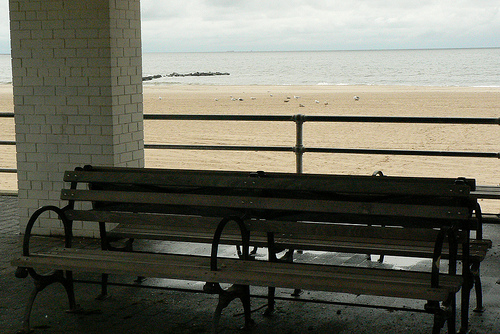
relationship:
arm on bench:
[405, 202, 483, 331] [11, 164, 491, 334]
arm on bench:
[3, 183, 85, 273] [11, 164, 491, 334]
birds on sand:
[196, 89, 263, 112] [0, 75, 500, 204]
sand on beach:
[0, 75, 500, 204] [0, 47, 498, 215]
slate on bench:
[58, 184, 490, 223] [11, 164, 491, 334]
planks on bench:
[15, 247, 466, 302] [11, 164, 491, 334]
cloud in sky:
[143, 0, 498, 47] [143, 7, 496, 50]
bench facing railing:
[11, 164, 491, 334] [137, 112, 499, 195]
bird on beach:
[309, 95, 324, 104] [7, 57, 499, 199]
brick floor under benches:
[2, 221, 499, 332] [15, 163, 491, 326]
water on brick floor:
[387, 256, 416, 268] [320, 251, 413, 324]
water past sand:
[18, 35, 455, 91] [140, 85, 498, 184]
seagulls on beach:
[233, 75, 394, 130] [378, 45, 467, 127]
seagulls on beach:
[217, 97, 372, 110] [390, 93, 499, 157]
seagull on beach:
[353, 92, 359, 100] [0, 47, 498, 215]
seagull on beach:
[324, 100, 329, 105] [0, 47, 498, 215]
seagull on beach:
[313, 98, 319, 104] [0, 47, 498, 215]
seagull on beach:
[298, 103, 305, 107] [0, 47, 498, 215]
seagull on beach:
[293, 95, 300, 99] [0, 47, 498, 215]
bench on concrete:
[11, 144, 497, 325] [27, 273, 429, 331]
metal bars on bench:
[22, 203, 72, 255] [11, 164, 491, 334]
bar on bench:
[197, 215, 257, 327] [11, 144, 497, 325]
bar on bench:
[418, 225, 478, 332] [81, 154, 496, 329]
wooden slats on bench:
[58, 170, 475, 241] [11, 164, 491, 334]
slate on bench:
[108, 179, 483, 264] [45, 138, 490, 309]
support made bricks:
[12, 67, 123, 155] [6, 3, 152, 238]